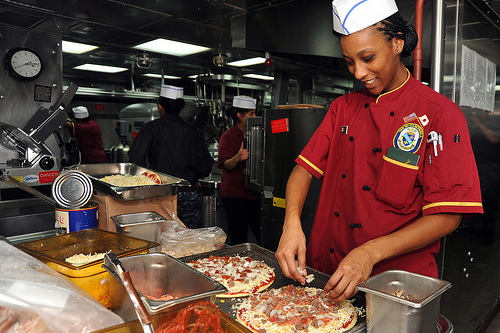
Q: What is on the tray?
A: Two pizzas.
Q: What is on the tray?
A: Two pizzas.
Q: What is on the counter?
A: Deli slicer.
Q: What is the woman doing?
A: Making pizza.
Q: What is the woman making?
A: Pizza.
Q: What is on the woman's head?
A: A paper hat.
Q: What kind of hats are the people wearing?
A: Paper hats.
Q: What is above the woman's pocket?
A: A ship's crest.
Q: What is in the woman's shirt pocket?
A: A notebook.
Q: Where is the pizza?
A: On the tray.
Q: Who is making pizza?
A: The woman in red.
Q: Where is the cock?
A: On the wall.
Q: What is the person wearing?
A: Hat.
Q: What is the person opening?
A: Industrial pizza oven.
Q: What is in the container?
A: Mozzarella cheese.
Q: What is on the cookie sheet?
A: Two made from scratch pizzas.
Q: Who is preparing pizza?
A: A woman.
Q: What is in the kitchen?
A: Cookers.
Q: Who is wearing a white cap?
A: The woman.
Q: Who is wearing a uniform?
A: The people.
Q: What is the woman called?
A: A chef.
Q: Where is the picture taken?
A: Kitchen.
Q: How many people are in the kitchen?
A: Four.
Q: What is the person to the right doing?
A: Making pizza.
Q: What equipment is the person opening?
A: Pizza oven.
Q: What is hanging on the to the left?
A: Clock.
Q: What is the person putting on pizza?
A: Grated cheese.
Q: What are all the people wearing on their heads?
A: Hats.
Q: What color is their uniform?
A: Red.